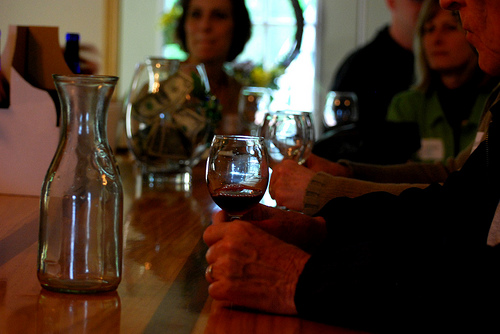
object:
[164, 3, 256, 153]
lady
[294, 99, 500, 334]
shirt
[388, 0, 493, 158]
woman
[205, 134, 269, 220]
glass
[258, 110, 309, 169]
glass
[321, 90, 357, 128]
glass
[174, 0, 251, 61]
hair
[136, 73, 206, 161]
bills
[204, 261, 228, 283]
man's finger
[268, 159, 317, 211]
hand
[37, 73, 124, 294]
bottle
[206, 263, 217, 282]
ring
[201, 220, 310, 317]
hands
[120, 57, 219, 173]
jar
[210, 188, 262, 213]
red wine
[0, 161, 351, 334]
counter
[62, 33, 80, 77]
bottle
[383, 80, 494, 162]
jacket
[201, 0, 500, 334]
man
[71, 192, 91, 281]
reflection